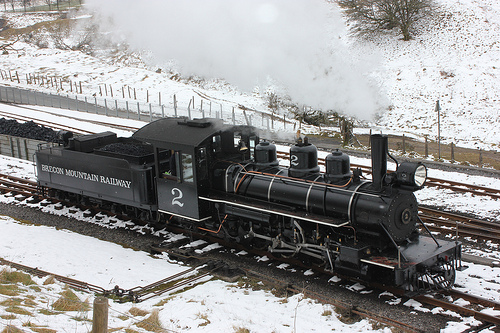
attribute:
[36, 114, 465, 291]
locomotive — old timey, black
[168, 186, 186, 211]
number — 2, white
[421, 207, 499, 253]
tracks — parallel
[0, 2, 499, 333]
photo — picturesque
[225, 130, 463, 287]
engine — black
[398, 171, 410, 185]
number — 2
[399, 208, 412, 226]
number — 2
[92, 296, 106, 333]
post — wooden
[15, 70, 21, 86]
post — wooden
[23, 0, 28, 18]
post — wooden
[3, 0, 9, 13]
post — wooden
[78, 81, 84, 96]
post — wooden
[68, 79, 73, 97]
post — wooden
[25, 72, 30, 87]
post — wooden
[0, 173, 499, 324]
track — snowy